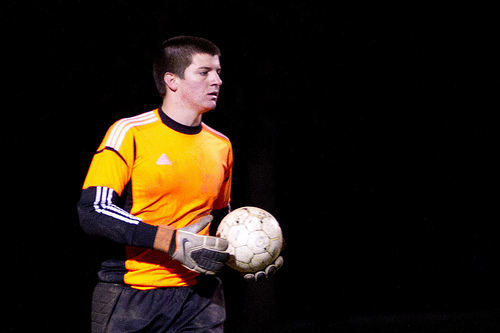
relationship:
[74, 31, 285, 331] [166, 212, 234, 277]
goalie wearing glove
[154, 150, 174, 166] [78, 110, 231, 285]
logo on shirt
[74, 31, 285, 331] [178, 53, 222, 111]
goalie has face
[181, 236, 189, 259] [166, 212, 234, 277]
logo on glove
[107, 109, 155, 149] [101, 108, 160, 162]
stripes on shoulder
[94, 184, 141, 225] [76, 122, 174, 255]
stripes on arm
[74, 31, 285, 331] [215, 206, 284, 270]
goalie has ball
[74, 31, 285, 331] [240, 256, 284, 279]
goalie wearing glove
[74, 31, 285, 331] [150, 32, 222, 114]
goalie has head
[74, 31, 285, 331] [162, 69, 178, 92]
goalie has ear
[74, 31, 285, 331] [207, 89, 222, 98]
goalie has mouth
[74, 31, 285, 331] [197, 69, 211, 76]
goalie has eye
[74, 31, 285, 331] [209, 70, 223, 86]
goalie has nose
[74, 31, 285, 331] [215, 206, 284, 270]
goalie holding ball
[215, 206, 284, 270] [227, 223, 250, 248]
ball has hexagon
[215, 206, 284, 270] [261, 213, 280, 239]
ball has hexagon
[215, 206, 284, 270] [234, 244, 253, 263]
ball has hexagon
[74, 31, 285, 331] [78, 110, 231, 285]
goalie wears shirt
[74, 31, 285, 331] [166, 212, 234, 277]
goalie wears glove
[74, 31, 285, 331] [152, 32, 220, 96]
goalie has hair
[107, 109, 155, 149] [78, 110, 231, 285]
stripes on shirt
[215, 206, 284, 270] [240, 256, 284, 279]
ball in glove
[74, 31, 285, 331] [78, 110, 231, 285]
goalie wearing shirt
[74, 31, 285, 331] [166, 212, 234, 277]
goalie has glove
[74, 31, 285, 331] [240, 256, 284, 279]
goalie has glove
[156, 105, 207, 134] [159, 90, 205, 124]
trim around neck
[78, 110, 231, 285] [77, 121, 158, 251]
shirt has sleeve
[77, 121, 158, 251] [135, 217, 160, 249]
sleeve has cuff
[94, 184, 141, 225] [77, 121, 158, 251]
stripes on sleeve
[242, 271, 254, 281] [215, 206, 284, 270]
finger under ball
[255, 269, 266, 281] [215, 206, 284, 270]
finger under ball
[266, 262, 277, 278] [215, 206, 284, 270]
finger under ball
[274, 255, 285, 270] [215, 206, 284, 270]
finger under ball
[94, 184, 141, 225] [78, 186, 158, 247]
stripes on sleeve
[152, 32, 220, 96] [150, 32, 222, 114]
hair on head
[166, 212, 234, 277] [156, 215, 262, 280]
glove on hand